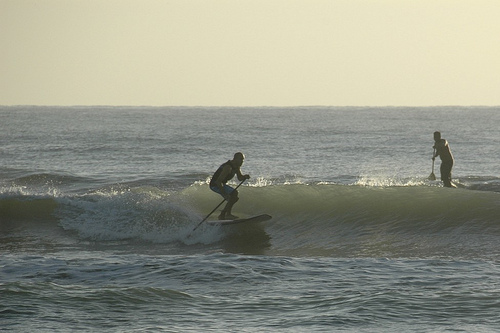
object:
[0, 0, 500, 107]
sky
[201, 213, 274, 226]
surf board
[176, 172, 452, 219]
wave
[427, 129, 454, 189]
man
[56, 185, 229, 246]
trail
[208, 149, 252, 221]
man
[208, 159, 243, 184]
jacket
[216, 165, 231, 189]
arm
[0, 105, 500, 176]
gentle portion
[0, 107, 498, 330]
water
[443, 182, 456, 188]
surfboard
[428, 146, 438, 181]
paddle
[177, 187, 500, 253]
wave front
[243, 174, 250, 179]
hand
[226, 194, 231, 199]
hand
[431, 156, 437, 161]
hand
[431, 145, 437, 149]
hand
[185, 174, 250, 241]
paddle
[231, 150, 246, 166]
head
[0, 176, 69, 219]
waves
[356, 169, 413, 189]
white curl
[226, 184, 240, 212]
leg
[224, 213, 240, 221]
foot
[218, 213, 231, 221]
foot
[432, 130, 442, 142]
head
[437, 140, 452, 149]
arm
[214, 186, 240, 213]
leg